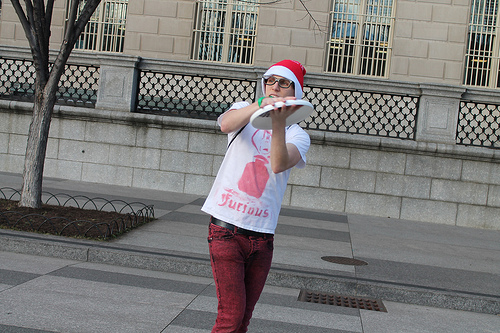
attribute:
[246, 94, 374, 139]
frisbee — white 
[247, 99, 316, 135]
frisbee — white 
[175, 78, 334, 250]
shirt — white 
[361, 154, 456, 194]
blocks — white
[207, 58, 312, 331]
boy — Young 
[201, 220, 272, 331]
pants — Red 